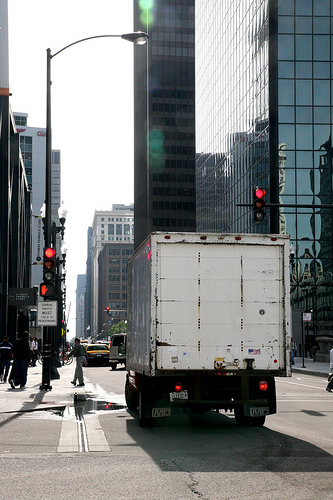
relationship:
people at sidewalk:
[1, 330, 35, 389] [26, 371, 45, 422]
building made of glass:
[144, 23, 271, 235] [277, 57, 318, 120]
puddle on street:
[35, 389, 144, 436] [96, 367, 119, 390]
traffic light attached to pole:
[32, 243, 68, 297] [40, 74, 62, 248]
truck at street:
[123, 215, 305, 407] [96, 367, 119, 390]